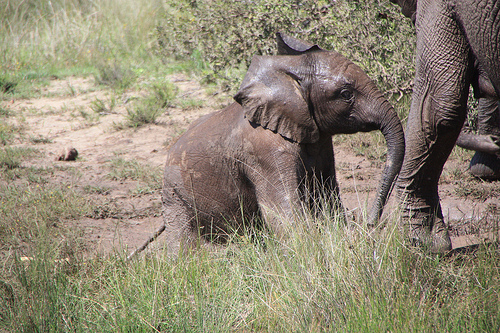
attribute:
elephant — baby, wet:
[122, 30, 407, 265]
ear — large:
[232, 54, 321, 145]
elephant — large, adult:
[390, 1, 499, 261]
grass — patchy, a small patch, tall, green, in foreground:
[0, 165, 499, 331]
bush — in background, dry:
[154, 2, 421, 104]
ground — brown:
[1, 1, 499, 253]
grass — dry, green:
[0, 1, 169, 77]